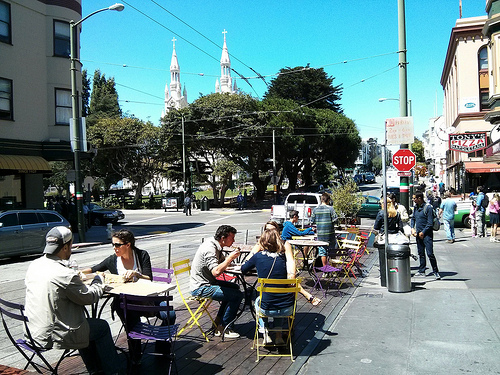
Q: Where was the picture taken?
A: On a street.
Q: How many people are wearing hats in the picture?
A: One.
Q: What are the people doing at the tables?
A: Eating.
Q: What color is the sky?
A: Blue.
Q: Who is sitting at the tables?
A: People.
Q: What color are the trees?
A: Green.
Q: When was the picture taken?
A: During the day.